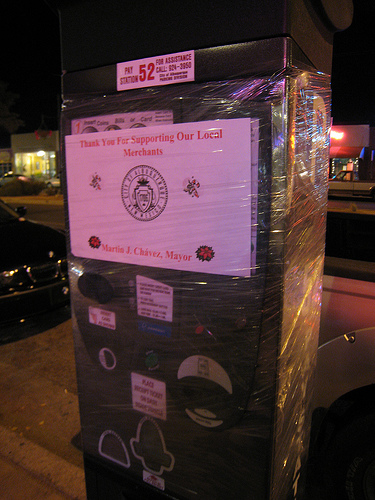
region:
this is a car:
[5, 213, 74, 289]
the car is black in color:
[15, 234, 30, 260]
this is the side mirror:
[13, 191, 37, 222]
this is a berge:
[117, 167, 175, 224]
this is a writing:
[78, 133, 231, 149]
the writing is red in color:
[96, 241, 196, 270]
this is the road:
[4, 347, 47, 434]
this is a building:
[13, 135, 55, 161]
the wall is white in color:
[14, 135, 28, 148]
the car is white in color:
[45, 175, 56, 187]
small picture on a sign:
[192, 241, 218, 266]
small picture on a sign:
[85, 232, 101, 249]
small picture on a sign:
[181, 174, 204, 201]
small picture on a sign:
[85, 169, 103, 193]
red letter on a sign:
[136, 60, 148, 84]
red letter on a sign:
[145, 60, 156, 83]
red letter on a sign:
[186, 253, 192, 262]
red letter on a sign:
[176, 252, 184, 262]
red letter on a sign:
[162, 247, 174, 261]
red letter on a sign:
[124, 242, 130, 255]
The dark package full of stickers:
[62, 36, 330, 499]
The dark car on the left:
[0, 198, 68, 339]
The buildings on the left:
[0, 130, 62, 183]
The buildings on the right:
[326, 125, 371, 220]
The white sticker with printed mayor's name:
[62, 120, 259, 277]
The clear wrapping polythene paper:
[62, 68, 332, 495]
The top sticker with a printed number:
[114, 47, 189, 87]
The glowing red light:
[331, 119, 353, 159]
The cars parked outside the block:
[0, 169, 61, 192]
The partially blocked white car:
[317, 269, 374, 498]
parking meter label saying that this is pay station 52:
[116, 48, 195, 93]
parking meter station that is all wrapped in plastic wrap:
[61, 0, 354, 499]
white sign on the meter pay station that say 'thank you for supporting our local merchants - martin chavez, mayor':
[63, 116, 251, 278]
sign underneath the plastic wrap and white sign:
[70, 107, 173, 135]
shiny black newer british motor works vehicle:
[0, 198, 70, 331]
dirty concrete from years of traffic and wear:
[0, 317, 85, 499]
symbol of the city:
[120, 164, 168, 221]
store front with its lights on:
[13, 149, 56, 177]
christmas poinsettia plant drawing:
[195, 245, 215, 262]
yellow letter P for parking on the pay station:
[309, 92, 326, 184]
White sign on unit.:
[61, 126, 263, 276]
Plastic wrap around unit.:
[70, 78, 333, 496]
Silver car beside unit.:
[319, 172, 373, 403]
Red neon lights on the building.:
[330, 122, 347, 144]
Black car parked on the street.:
[1, 197, 71, 326]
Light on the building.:
[31, 147, 46, 158]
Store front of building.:
[11, 131, 62, 177]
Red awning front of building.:
[329, 142, 369, 158]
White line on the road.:
[1, 417, 87, 496]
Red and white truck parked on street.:
[327, 167, 372, 197]